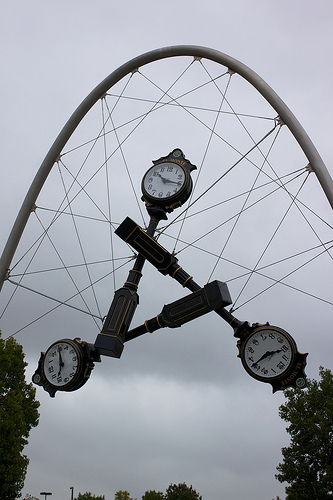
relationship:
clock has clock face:
[94, 146, 198, 358] [139, 147, 199, 214]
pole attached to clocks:
[93, 215, 158, 360] [136, 144, 199, 216]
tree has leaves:
[271, 365, 331, 498] [271, 365, 331, 498]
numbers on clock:
[276, 360, 284, 369] [35, 335, 95, 393]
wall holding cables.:
[269, 98, 286, 120] [237, 190, 283, 277]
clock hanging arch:
[141, 160, 193, 202] [114, 50, 280, 134]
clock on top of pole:
[36, 334, 98, 389] [113, 135, 267, 242]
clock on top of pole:
[244, 330, 291, 377] [179, 276, 235, 328]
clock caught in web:
[41, 338, 83, 389] [105, 84, 235, 149]